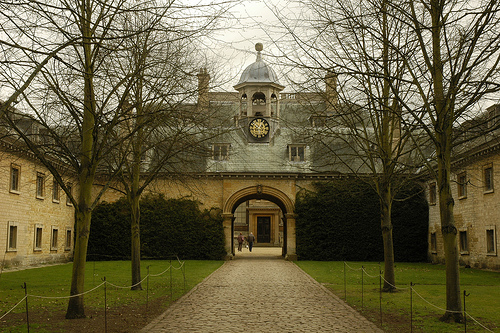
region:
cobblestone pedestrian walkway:
[133, 248, 388, 331]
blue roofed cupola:
[231, 37, 286, 120]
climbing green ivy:
[298, 173, 429, 262]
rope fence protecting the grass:
[338, 256, 497, 331]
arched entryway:
[220, 180, 298, 261]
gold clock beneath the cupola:
[248, 117, 270, 142]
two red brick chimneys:
[191, 65, 337, 107]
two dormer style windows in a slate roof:
[205, 133, 310, 160]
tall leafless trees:
[287, 45, 477, 305]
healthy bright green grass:
[0, 257, 227, 315]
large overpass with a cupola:
[102, 40, 408, 270]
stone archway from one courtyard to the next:
[219, 171, 305, 271]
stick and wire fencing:
[42, 266, 214, 320]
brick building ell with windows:
[2, 142, 97, 275]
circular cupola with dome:
[228, 39, 295, 156]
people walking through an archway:
[234, 227, 264, 253]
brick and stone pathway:
[168, 251, 335, 326]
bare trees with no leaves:
[24, 9, 162, 305]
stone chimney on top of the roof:
[187, 60, 216, 117]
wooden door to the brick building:
[245, 201, 280, 263]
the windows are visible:
[21, 166, 74, 249]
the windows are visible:
[20, 133, 130, 287]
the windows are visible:
[3, 146, 189, 331]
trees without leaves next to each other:
[16, 7, 183, 314]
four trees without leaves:
[14, 7, 489, 321]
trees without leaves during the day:
[22, 7, 220, 317]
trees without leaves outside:
[10, 6, 214, 319]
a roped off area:
[14, 260, 247, 315]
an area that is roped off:
[16, 262, 233, 331]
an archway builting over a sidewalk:
[214, 146, 334, 276]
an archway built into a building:
[212, 175, 367, 297]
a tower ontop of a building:
[216, 22, 310, 167]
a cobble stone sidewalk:
[210, 195, 313, 330]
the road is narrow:
[142, 192, 314, 329]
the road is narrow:
[197, 210, 288, 326]